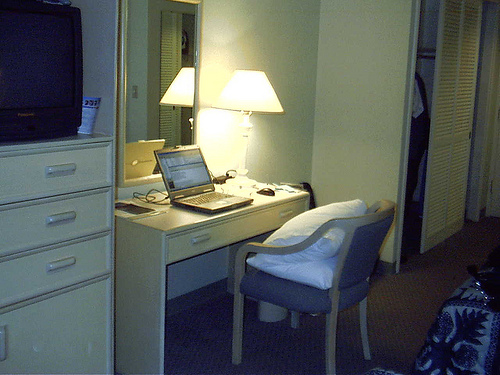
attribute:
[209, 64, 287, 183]
lamp — on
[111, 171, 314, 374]
desk — wood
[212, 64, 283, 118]
lampshade — white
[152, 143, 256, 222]
laptop — open, grey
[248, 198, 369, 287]
pillows — fluffy, white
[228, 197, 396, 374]
chair — blue, beige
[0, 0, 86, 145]
tv — black, off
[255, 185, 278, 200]
mouse — black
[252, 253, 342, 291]
pillow — white, large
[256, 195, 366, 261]
pillow — white, large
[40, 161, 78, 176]
drawer handle — white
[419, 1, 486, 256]
closet door — open